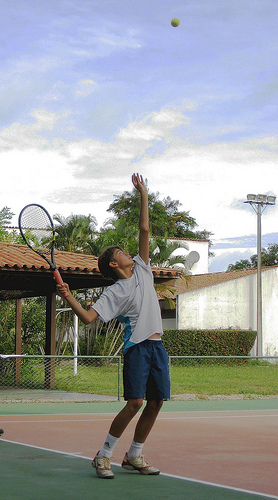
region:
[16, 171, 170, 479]
a young boy tennis player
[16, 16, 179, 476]
a tennis player serving ball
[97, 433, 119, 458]
a tall white sock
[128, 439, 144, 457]
a tall white sock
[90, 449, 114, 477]
a red and white shoe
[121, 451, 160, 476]
a red and white shoe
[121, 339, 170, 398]
a pair of blue board shorts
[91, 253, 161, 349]
a grey and blue t-shirt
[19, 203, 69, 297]
a black and orange tennis racket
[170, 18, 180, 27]
a yellow tennis ball in air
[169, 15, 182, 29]
the ball is in the air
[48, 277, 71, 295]
he is holding the racket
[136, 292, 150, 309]
the shirt is gray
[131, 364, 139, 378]
the shorts are blue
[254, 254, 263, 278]
the pole is gray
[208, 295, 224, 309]
the building is white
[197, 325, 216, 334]
the bush is by the building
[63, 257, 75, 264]
the roof is brown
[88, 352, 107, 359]
the pole is green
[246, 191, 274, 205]
the lights are off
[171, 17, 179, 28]
a yellow ball in the air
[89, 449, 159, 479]
yellow and red sneakers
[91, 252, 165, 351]
a white shirt with a blue line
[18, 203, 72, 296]
a young man holding a tennis racket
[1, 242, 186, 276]
an orange roof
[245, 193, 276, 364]
floodlights on the other side of a fence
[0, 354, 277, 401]
a green fence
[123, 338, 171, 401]
young man wearing blue shorts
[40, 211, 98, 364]
a palm tree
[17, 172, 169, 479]
a young man playing tennis on a tennis court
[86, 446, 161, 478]
Boy wearing shoes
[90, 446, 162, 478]
Boy is wearing shoes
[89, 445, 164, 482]
Boy wearing white and red shoes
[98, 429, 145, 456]
Boy wearing socks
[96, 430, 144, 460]
Boy is wearing socks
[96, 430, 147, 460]
Boy wearing white socks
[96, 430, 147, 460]
Boy is wearing white socks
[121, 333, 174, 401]
Boy wearing blue shorts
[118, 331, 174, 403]
Boy is wearing blue shorts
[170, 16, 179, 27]
the ball is in mid air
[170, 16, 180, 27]
the ball is green in color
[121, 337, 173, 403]
the boy is wearing shorts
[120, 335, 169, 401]
the shorts are blue in color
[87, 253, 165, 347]
the boy is wearing a short sleeve shirt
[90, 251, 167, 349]
the boy is wearing a white shirt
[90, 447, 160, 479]
the boy is wearing sneakers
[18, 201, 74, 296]
the boy is holding a racket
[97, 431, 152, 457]
the boy is wearing white socks